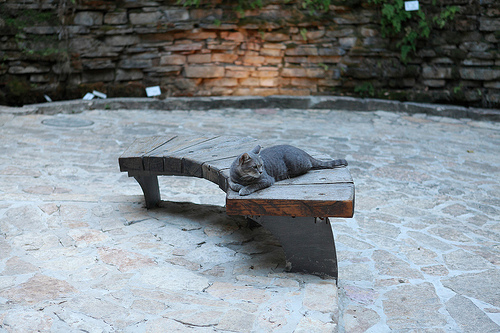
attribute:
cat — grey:
[217, 135, 348, 210]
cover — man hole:
[35, 105, 97, 145]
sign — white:
[141, 80, 177, 101]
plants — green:
[6, 0, 495, 67]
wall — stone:
[4, 2, 499, 115]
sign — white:
[406, 0, 418, 19]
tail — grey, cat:
[305, 148, 348, 182]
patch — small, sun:
[163, 31, 344, 101]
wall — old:
[48, 14, 403, 90]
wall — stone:
[18, 3, 472, 101]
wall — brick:
[37, 11, 464, 103]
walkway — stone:
[366, 123, 497, 283]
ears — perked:
[240, 145, 264, 165]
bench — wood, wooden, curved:
[118, 127, 359, 281]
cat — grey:
[219, 134, 349, 190]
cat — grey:
[222, 140, 355, 195]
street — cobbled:
[357, 134, 479, 322]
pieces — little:
[79, 81, 168, 99]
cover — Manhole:
[40, 110, 97, 131]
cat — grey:
[223, 135, 351, 195]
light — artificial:
[175, 17, 332, 89]